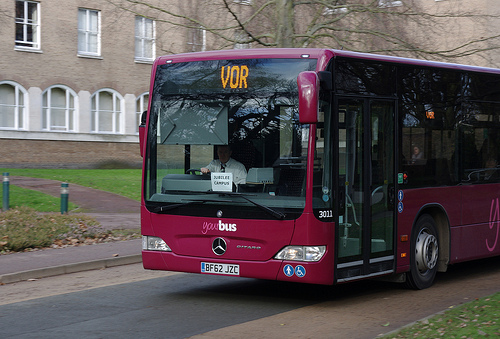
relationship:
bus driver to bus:
[200, 144, 248, 193] [136, 49, 496, 288]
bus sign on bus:
[220, 66, 248, 88] [136, 49, 496, 288]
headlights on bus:
[139, 232, 328, 262] [120, 18, 498, 314]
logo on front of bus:
[209, 235, 233, 257] [136, 49, 496, 288]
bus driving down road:
[136, 49, 496, 288] [4, 260, 497, 335]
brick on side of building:
[57, 58, 69, 64] [0, 0, 499, 167]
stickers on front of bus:
[281, 265, 313, 279] [136, 49, 496, 288]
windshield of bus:
[154, 97, 308, 213] [136, 49, 496, 288]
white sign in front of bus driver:
[209, 171, 236, 193] [198, 145, 246, 190]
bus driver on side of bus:
[200, 144, 248, 193] [136, 49, 496, 288]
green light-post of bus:
[56, 180, 76, 213] [136, 49, 496, 288]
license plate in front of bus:
[201, 262, 240, 274] [129, 30, 473, 293]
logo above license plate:
[211, 237, 226, 255] [190, 261, 239, 282]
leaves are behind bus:
[5, 208, 135, 264] [136, 49, 496, 288]